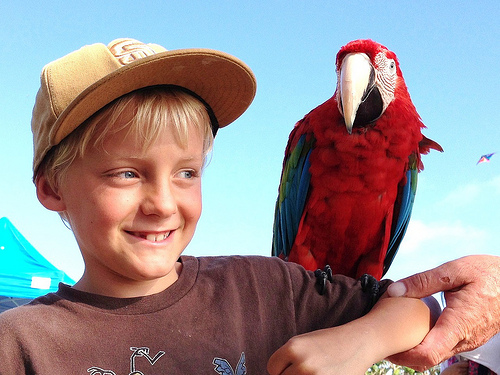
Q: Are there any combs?
A: No, there are no combs.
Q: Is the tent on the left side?
A: Yes, the tent is on the left of the image.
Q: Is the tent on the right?
A: No, the tent is on the left of the image.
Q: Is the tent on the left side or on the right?
A: The tent is on the left of the image.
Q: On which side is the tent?
A: The tent is on the left of the image.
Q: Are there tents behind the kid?
A: Yes, there is a tent behind the kid.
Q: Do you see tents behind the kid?
A: Yes, there is a tent behind the kid.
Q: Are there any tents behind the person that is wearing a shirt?
A: Yes, there is a tent behind the kid.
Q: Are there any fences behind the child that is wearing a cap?
A: No, there is a tent behind the child.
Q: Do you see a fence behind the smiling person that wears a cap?
A: No, there is a tent behind the child.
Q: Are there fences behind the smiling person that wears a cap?
A: No, there is a tent behind the child.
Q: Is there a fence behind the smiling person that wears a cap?
A: No, there is a tent behind the child.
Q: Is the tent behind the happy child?
A: Yes, the tent is behind the kid.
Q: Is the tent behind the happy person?
A: Yes, the tent is behind the kid.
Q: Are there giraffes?
A: No, there are no giraffes.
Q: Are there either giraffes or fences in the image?
A: No, there are no giraffes or fences.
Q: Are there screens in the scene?
A: No, there are no screens.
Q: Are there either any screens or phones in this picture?
A: No, there are no screens or phones.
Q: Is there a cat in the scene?
A: No, there are no cats.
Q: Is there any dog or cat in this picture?
A: No, there are no cats or dogs.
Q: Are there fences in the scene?
A: No, there are no fences.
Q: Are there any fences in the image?
A: No, there are no fences.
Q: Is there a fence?
A: No, there are no fences.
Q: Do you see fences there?
A: No, there are no fences.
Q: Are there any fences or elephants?
A: No, there are no fences or elephants.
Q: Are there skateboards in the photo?
A: No, there are no skateboards.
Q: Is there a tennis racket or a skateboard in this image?
A: No, there are no skateboards or rackets.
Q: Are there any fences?
A: No, there are no fences.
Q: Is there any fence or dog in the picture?
A: No, there are no fences or dogs.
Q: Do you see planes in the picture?
A: No, there are no planes.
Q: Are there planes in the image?
A: No, there are no planes.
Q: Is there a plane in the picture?
A: No, there are no airplanes.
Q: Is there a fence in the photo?
A: No, there are no fences.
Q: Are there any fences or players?
A: No, there are no fences or players.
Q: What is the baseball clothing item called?
A: The clothing item is a cap.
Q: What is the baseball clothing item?
A: The clothing item is a cap.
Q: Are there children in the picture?
A: Yes, there is a child.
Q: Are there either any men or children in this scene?
A: Yes, there is a child.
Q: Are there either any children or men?
A: Yes, there is a child.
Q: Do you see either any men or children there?
A: Yes, there is a child.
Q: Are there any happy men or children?
A: Yes, there is a happy child.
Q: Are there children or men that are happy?
A: Yes, the child is happy.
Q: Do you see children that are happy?
A: Yes, there is a happy child.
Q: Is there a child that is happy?
A: Yes, there is a child that is happy.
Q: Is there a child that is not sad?
A: Yes, there is a happy child.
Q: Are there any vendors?
A: No, there are no vendors.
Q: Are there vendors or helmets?
A: No, there are no vendors or helmets.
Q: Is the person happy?
A: Yes, the kid is happy.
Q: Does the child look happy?
A: Yes, the child is happy.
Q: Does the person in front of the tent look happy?
A: Yes, the child is happy.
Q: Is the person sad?
A: No, the kid is happy.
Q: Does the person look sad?
A: No, the kid is happy.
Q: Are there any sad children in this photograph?
A: No, there is a child but he is happy.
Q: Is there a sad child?
A: No, there is a child but he is happy.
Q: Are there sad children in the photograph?
A: No, there is a child but he is happy.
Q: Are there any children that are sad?
A: No, there is a child but he is happy.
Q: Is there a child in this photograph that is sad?
A: No, there is a child but he is happy.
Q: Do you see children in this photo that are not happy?
A: No, there is a child but he is happy.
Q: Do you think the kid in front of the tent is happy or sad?
A: The child is happy.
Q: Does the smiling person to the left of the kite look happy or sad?
A: The child is happy.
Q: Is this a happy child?
A: Yes, this is a happy child.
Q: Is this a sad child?
A: No, this is a happy child.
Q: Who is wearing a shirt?
A: The child is wearing a shirt.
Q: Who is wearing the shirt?
A: The child is wearing a shirt.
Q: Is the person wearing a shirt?
A: Yes, the kid is wearing a shirt.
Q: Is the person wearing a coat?
A: No, the child is wearing a shirt.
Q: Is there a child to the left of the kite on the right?
A: Yes, there is a child to the left of the kite.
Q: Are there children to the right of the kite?
A: No, the child is to the left of the kite.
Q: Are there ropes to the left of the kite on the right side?
A: No, there is a child to the left of the kite.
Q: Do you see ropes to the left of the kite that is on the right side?
A: No, there is a child to the left of the kite.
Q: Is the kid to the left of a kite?
A: Yes, the kid is to the left of a kite.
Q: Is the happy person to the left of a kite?
A: Yes, the kid is to the left of a kite.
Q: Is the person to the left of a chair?
A: No, the kid is to the left of a kite.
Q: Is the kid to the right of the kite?
A: No, the kid is to the left of the kite.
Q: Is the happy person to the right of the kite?
A: No, the kid is to the left of the kite.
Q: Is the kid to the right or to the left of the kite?
A: The kid is to the left of the kite.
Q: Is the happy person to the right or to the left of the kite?
A: The kid is to the left of the kite.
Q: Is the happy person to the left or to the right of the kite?
A: The kid is to the left of the kite.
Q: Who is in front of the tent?
A: The kid is in front of the tent.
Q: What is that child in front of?
A: The child is in front of the tent.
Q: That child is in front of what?
A: The child is in front of the tent.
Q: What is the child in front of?
A: The child is in front of the tent.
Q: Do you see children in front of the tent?
A: Yes, there is a child in front of the tent.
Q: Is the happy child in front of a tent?
A: Yes, the kid is in front of a tent.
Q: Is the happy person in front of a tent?
A: Yes, the kid is in front of a tent.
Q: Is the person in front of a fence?
A: No, the child is in front of a tent.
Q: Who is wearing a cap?
A: The child is wearing a cap.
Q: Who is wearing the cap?
A: The child is wearing a cap.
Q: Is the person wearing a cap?
A: Yes, the kid is wearing a cap.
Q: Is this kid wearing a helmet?
A: No, the kid is wearing a cap.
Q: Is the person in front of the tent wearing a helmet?
A: No, the kid is wearing a cap.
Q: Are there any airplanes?
A: No, there are no airplanes.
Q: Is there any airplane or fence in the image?
A: No, there are no airplanes or fences.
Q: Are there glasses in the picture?
A: No, there are no glasses.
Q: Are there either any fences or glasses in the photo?
A: No, there are no glasses or fences.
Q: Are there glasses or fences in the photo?
A: No, there are no glasses or fences.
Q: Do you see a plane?
A: No, there are no airplanes.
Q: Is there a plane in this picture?
A: No, there are no airplanes.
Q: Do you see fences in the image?
A: No, there are no fences.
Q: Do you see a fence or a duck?
A: No, there are no fences or ducks.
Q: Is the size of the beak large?
A: Yes, the beak is large.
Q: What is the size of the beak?
A: The beak is large.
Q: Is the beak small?
A: No, the beak is large.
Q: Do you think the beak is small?
A: No, the beak is large.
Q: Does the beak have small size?
A: No, the beak is large.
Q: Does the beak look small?
A: No, the beak is large.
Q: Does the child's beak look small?
A: No, the beak is large.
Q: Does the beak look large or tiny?
A: The beak is large.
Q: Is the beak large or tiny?
A: The beak is large.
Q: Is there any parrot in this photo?
A: Yes, there is a parrot.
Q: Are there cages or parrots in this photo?
A: Yes, there is a parrot.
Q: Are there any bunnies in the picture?
A: No, there are no bunnies.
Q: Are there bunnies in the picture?
A: No, there are no bunnies.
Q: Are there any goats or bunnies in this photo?
A: No, there are no bunnies or goats.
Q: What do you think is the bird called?
A: The bird is a parrot.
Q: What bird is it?
A: The bird is a parrot.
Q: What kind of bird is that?
A: This is a parrot.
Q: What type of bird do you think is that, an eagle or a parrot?
A: This is a parrot.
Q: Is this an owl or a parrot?
A: This is a parrot.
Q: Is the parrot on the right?
A: Yes, the parrot is on the right of the image.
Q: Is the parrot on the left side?
A: No, the parrot is on the right of the image.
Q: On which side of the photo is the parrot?
A: The parrot is on the right of the image.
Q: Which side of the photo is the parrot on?
A: The parrot is on the right of the image.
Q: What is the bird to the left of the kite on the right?
A: The bird is a parrot.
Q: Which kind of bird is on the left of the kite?
A: The bird is a parrot.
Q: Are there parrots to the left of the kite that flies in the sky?
A: Yes, there is a parrot to the left of the kite.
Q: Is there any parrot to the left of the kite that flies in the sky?
A: Yes, there is a parrot to the left of the kite.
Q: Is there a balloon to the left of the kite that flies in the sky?
A: No, there is a parrot to the left of the kite.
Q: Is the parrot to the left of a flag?
A: No, the parrot is to the left of a kite.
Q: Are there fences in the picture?
A: No, there are no fences.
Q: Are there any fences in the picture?
A: No, there are no fences.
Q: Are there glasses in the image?
A: No, there are no glasses.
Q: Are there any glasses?
A: No, there are no glasses.